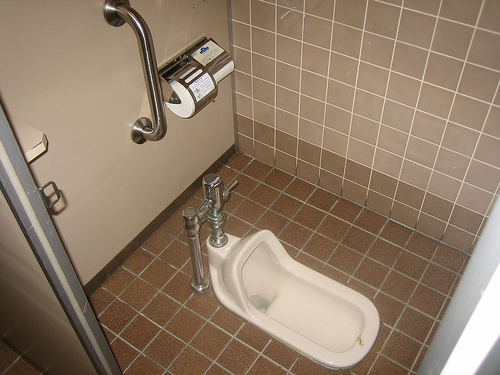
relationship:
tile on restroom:
[327, 18, 367, 63] [4, 3, 496, 373]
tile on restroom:
[391, 5, 441, 56] [4, 3, 496, 373]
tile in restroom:
[311, 210, 358, 249] [4, 3, 496, 373]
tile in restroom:
[327, 18, 367, 63] [4, 3, 496, 373]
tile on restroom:
[142, 325, 192, 372] [4, 3, 496, 373]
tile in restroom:
[391, 5, 441, 56] [4, 3, 496, 373]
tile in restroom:
[142, 325, 192, 372] [4, 3, 496, 373]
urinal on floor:
[198, 226, 387, 373] [66, 150, 476, 373]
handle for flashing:
[221, 176, 246, 204] [224, 175, 244, 196]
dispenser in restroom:
[157, 62, 222, 121] [4, 3, 496, 373]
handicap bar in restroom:
[101, 2, 169, 146] [4, 3, 496, 373]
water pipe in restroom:
[206, 211, 230, 247] [4, 3, 496, 373]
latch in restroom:
[40, 178, 65, 213] [4, 3, 496, 373]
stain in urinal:
[356, 334, 364, 347] [198, 226, 387, 373]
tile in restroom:
[393, 301, 439, 344] [4, 3, 496, 373]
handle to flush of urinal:
[221, 176, 246, 204] [198, 226, 387, 373]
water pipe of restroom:
[206, 211, 230, 247] [4, 3, 496, 373]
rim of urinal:
[256, 315, 326, 361] [198, 226, 387, 373]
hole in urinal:
[252, 288, 271, 311] [198, 226, 387, 373]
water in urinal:
[260, 299, 266, 306] [198, 226, 387, 373]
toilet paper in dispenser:
[166, 82, 196, 119] [157, 62, 222, 121]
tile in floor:
[311, 210, 358, 249] [66, 150, 476, 373]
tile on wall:
[327, 18, 367, 63] [230, 2, 500, 259]